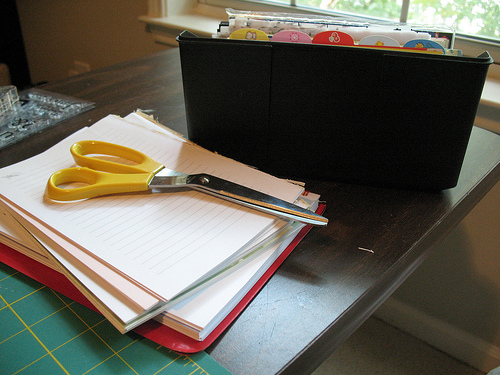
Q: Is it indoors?
A: Yes, it is indoors.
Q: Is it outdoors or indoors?
A: It is indoors.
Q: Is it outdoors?
A: No, it is indoors.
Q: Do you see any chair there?
A: No, there are no chairs.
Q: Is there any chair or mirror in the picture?
A: No, there are no chairs or mirrors.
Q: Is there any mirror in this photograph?
A: No, there are no mirrors.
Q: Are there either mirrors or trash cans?
A: No, there are no mirrors or trash cans.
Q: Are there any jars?
A: No, there are no jars.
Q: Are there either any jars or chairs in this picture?
A: No, there are no jars or chairs.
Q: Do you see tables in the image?
A: Yes, there is a table.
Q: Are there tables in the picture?
A: Yes, there is a table.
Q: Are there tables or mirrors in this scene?
A: Yes, there is a table.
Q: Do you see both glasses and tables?
A: No, there is a table but no glasses.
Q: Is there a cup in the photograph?
A: No, there are no cups.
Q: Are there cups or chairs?
A: No, there are no cups or chairs.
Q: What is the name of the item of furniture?
A: The piece of furniture is a table.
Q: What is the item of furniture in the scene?
A: The piece of furniture is a table.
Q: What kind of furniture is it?
A: The piece of furniture is a table.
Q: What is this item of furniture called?
A: This is a table.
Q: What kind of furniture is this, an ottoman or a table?
A: This is a table.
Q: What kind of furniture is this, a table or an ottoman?
A: This is a table.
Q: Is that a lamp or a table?
A: That is a table.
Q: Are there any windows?
A: Yes, there is a window.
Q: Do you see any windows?
A: Yes, there is a window.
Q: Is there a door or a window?
A: Yes, there is a window.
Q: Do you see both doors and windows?
A: No, there is a window but no doors.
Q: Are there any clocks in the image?
A: No, there are no clocks.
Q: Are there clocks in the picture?
A: No, there are no clocks.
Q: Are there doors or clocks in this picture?
A: No, there are no clocks or doors.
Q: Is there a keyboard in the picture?
A: No, there are no keyboards.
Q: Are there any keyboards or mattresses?
A: No, there are no keyboards or mattresses.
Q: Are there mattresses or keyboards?
A: No, there are no keyboards or mattresses.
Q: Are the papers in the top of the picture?
A: Yes, the papers are in the top of the image.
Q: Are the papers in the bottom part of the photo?
A: No, the papers are in the top of the image.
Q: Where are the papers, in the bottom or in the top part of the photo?
A: The papers are in the top of the image.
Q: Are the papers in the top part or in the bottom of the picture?
A: The papers are in the top of the image.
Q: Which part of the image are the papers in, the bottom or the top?
A: The papers are in the top of the image.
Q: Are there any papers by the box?
A: Yes, there are papers by the box.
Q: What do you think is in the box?
A: The papers are in the box.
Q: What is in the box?
A: The papers are in the box.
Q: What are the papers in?
A: The papers are in the box.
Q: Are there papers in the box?
A: Yes, there are papers in the box.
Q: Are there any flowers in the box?
A: No, there are papers in the box.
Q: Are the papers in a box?
A: Yes, the papers are in a box.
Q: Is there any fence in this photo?
A: No, there are no fences.